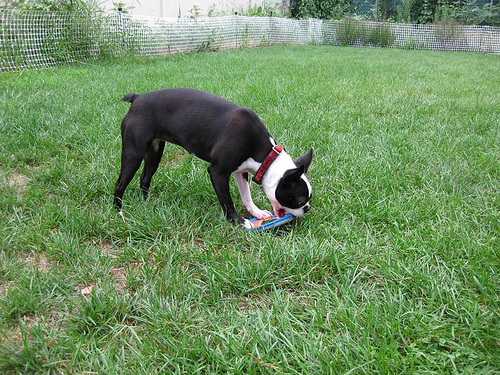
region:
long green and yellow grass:
[181, 263, 278, 337]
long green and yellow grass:
[35, 92, 73, 147]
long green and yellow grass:
[21, 205, 81, 277]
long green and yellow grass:
[264, 73, 341, 117]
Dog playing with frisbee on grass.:
[82, 75, 334, 241]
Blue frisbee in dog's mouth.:
[240, 205, 300, 237]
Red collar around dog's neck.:
[248, 131, 285, 184]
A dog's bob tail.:
[108, 81, 145, 108]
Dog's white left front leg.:
[230, 172, 278, 222]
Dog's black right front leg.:
[203, 171, 255, 238]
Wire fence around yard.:
[130, 9, 400, 54]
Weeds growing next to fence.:
[333, 15, 475, 54]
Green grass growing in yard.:
[311, 72, 479, 168]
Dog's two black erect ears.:
[281, 141, 321, 191]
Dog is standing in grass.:
[79, 78, 316, 256]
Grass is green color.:
[276, 62, 498, 187]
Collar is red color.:
[242, 132, 286, 193]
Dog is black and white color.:
[105, 83, 322, 242]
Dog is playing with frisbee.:
[100, 81, 322, 245]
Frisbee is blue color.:
[196, 171, 328, 241]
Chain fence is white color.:
[5, 10, 491, 67]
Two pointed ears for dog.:
[281, 146, 318, 188]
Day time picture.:
[7, 14, 492, 363]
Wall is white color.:
[118, 0, 295, 35]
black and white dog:
[101, 63, 341, 255]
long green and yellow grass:
[215, 248, 257, 299]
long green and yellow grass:
[142, 259, 217, 296]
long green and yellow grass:
[348, 69, 436, 114]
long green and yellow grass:
[34, 89, 74, 119]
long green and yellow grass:
[75, 305, 147, 336]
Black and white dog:
[110, 87, 317, 233]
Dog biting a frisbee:
[111, 86, 316, 231]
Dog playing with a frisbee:
[110, 85, 315, 235]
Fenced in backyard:
[0, 8, 495, 371]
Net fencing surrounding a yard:
[0, 5, 498, 75]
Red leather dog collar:
[252, 140, 284, 187]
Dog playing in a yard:
[111, 83, 317, 233]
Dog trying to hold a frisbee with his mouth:
[107, 85, 314, 235]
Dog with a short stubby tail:
[109, 85, 316, 236]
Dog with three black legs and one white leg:
[109, 86, 316, 241]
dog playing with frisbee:
[106, 83, 318, 236]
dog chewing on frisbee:
[103, 83, 318, 236]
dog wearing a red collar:
[108, 88, 330, 245]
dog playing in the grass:
[105, 83, 320, 250]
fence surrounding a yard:
[10, 5, 226, 72]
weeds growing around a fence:
[313, 10, 499, 57]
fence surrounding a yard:
[328, 12, 493, 59]